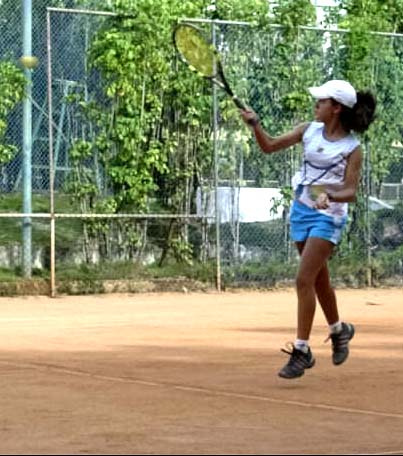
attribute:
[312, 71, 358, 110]
hat — white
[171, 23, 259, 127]
tennis racket — yellow, black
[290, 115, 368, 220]
shirt — white, sleeveless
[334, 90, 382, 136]
hair — dark black, curly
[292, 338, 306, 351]
socks — white, anklet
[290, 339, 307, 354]
sock — white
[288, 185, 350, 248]
shorts — blue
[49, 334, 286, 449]
court — clay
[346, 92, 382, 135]
hair — tied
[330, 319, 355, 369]
shoe — grey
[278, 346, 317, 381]
shoe — grey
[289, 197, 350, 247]
shorts — light blue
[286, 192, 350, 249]
shorts — blue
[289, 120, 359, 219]
shirt — white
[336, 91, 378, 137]
hair — dark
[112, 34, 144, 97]
leaves — green